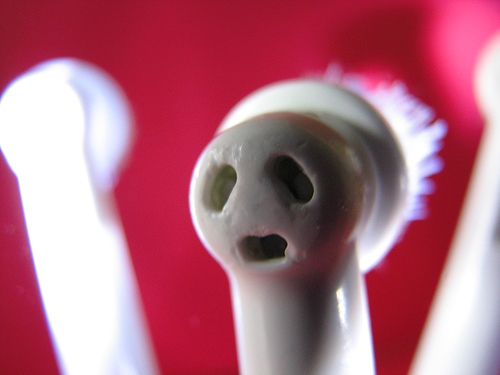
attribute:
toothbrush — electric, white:
[188, 62, 449, 374]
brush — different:
[5, 56, 173, 373]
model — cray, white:
[185, 114, 380, 374]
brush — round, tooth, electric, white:
[175, 48, 453, 372]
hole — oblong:
[267, 148, 321, 204]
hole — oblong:
[233, 232, 293, 265]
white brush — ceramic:
[205, 76, 441, 319]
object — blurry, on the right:
[399, 30, 499, 374]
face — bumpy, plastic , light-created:
[195, 152, 327, 266]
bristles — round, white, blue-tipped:
[343, 90, 487, 212]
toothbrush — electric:
[181, 111, 421, 321]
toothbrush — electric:
[211, 77, 415, 373]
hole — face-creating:
[261, 146, 323, 213]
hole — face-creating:
[189, 152, 246, 222]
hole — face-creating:
[219, 224, 300, 281]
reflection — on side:
[333, 285, 348, 332]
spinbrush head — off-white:
[192, 69, 456, 274]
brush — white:
[185, 50, 447, 346]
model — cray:
[184, 57, 449, 372]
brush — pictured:
[183, 75, 409, 373]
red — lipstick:
[103, 26, 264, 71]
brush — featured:
[181, 60, 459, 312]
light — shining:
[132, 90, 429, 333]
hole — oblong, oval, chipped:
[200, 160, 238, 216]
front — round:
[220, 78, 416, 267]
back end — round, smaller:
[188, 116, 374, 278]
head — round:
[208, 78, 410, 275]